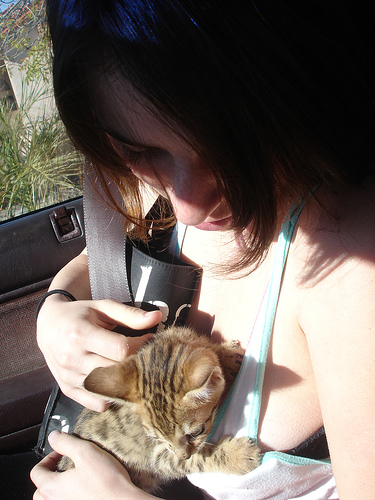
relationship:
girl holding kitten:
[30, 5, 374, 497] [44, 325, 262, 491]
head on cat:
[82, 338, 226, 460] [59, 324, 260, 491]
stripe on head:
[142, 338, 190, 438] [82, 338, 226, 460]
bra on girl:
[279, 421, 338, 462] [30, 5, 374, 497]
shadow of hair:
[305, 211, 367, 282] [50, 2, 365, 248]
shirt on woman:
[87, 178, 311, 376] [61, 15, 367, 469]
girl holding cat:
[10, 5, 374, 489] [59, 324, 260, 491]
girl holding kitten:
[30, 5, 374, 497] [45, 322, 263, 482]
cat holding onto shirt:
[59, 324, 260, 491] [164, 221, 340, 500]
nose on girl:
[160, 159, 228, 230] [30, 5, 374, 497]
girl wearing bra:
[30, 5, 374, 497] [276, 423, 330, 461]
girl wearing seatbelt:
[30, 5, 374, 497] [60, 178, 275, 467]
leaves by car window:
[6, 102, 16, 126] [1, 1, 82, 221]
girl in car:
[30, 5, 374, 497] [3, 190, 117, 403]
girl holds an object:
[30, 5, 374, 497] [110, 238, 205, 323]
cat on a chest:
[59, 324, 260, 491] [146, 218, 324, 454]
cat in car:
[53, 325, 262, 496] [3, 1, 372, 497]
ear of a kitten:
[82, 358, 141, 403] [50, 327, 263, 497]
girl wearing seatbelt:
[10, 5, 374, 489] [71, 147, 134, 308]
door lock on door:
[47, 203, 85, 243] [7, 156, 132, 282]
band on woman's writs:
[36, 289, 79, 322] [35, 281, 90, 356]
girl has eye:
[30, 5, 374, 497] [97, 135, 154, 163]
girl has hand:
[30, 5, 374, 497] [73, 243, 144, 438]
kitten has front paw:
[44, 325, 262, 491] [216, 435, 258, 477]